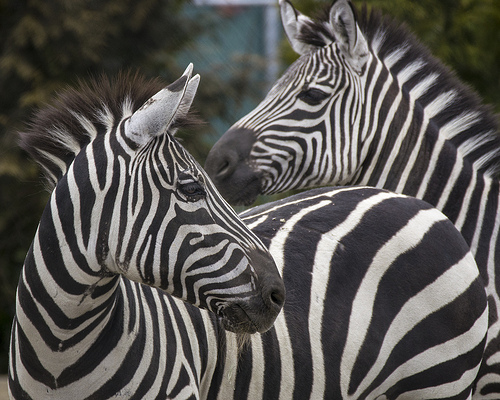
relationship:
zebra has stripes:
[2, 57, 494, 398] [289, 206, 445, 376]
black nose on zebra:
[261, 273, 288, 317] [2, 57, 494, 398]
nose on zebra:
[263, 244, 279, 334] [7, 84, 496, 317]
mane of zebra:
[361, 12, 496, 170] [204, 5, 499, 301]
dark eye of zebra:
[297, 88, 331, 106] [2, 57, 494, 398]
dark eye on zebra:
[252, 73, 388, 124] [163, 159, 200, 279]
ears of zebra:
[124, 63, 194, 145] [2, 57, 494, 398]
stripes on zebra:
[51, 223, 113, 400] [45, 53, 482, 385]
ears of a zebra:
[112, 54, 209, 158] [2, 57, 494, 398]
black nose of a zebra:
[262, 284, 286, 312] [264, 236, 273, 344]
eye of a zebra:
[178, 182, 204, 196] [20, 83, 482, 373]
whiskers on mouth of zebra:
[218, 318, 255, 353] [56, 150, 129, 229]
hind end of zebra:
[376, 198, 434, 313] [2, 57, 494, 398]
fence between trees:
[180, 0, 283, 175] [0, 3, 217, 153]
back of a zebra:
[148, 181, 410, 241] [2, 57, 494, 398]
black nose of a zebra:
[262, 284, 286, 312] [2, 57, 494, 398]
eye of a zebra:
[282, 75, 374, 124] [211, 36, 476, 273]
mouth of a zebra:
[218, 300, 270, 336] [2, 57, 494, 398]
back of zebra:
[148, 186, 408, 306] [16, 89, 473, 399]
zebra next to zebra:
[2, 57, 494, 398] [206, 6, 497, 395]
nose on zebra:
[211, 158, 238, 181] [206, 6, 497, 395]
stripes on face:
[124, 140, 265, 313] [119, 129, 285, 336]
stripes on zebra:
[124, 140, 265, 313] [16, 89, 473, 399]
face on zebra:
[119, 129, 285, 336] [16, 89, 473, 399]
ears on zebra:
[127, 61, 198, 141] [2, 57, 494, 398]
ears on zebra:
[274, 1, 367, 64] [206, 6, 497, 395]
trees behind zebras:
[0, 3, 499, 333] [8, 0, 498, 398]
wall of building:
[217, 24, 258, 46] [194, 10, 282, 70]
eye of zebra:
[178, 182, 204, 196] [2, 57, 494, 398]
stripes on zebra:
[241, 184, 483, 396] [279, 185, 484, 384]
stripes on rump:
[241, 184, 483, 396] [272, 186, 489, 397]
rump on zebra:
[272, 186, 489, 397] [279, 185, 484, 384]